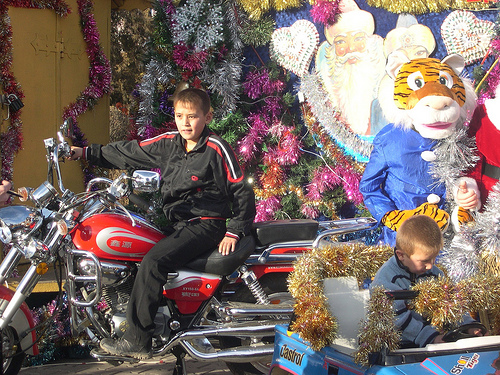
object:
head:
[384, 48, 468, 140]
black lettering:
[277, 344, 303, 366]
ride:
[275, 278, 500, 375]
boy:
[368, 215, 483, 347]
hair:
[394, 215, 442, 258]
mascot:
[358, 56, 479, 250]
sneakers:
[97, 331, 158, 364]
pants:
[100, 219, 224, 359]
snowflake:
[170, 0, 224, 53]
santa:
[316, 1, 386, 137]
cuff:
[221, 225, 243, 240]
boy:
[64, 86, 256, 359]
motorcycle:
[3, 114, 380, 373]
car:
[270, 276, 499, 375]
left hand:
[215, 235, 243, 258]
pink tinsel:
[58, 2, 113, 192]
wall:
[11, 0, 112, 196]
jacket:
[83, 130, 256, 239]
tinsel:
[47, 0, 112, 187]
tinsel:
[0, 0, 75, 191]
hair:
[170, 85, 210, 118]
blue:
[272, 329, 320, 374]